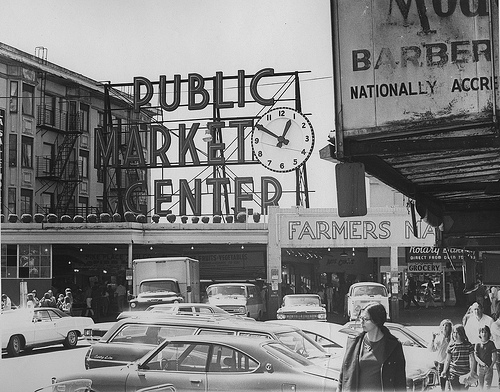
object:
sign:
[280, 213, 437, 243]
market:
[6, 184, 448, 316]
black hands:
[275, 119, 292, 148]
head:
[118, 279, 124, 285]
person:
[113, 281, 128, 307]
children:
[433, 301, 498, 383]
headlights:
[274, 311, 286, 318]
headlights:
[318, 311, 328, 320]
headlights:
[131, 302, 136, 308]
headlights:
[237, 305, 248, 314]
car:
[52, 333, 344, 390]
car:
[344, 279, 391, 304]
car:
[272, 292, 331, 322]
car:
[204, 281, 266, 319]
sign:
[88, 55, 321, 220]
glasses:
[356, 313, 371, 323]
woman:
[333, 300, 410, 390]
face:
[358, 306, 377, 334]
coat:
[339, 329, 409, 389]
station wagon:
[18, 267, 425, 389]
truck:
[130, 258, 198, 300]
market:
[4, 216, 285, 309]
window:
[208, 345, 259, 367]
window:
[142, 340, 211, 368]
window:
[111, 323, 191, 338]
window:
[32, 310, 45, 316]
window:
[48, 308, 60, 315]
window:
[198, 330, 233, 337]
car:
[87, 312, 315, 365]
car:
[1, 297, 96, 355]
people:
[3, 288, 75, 318]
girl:
[440, 317, 471, 390]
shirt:
[446, 340, 473, 371]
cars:
[50, 305, 340, 384]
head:
[63, 296, 71, 303]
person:
[61, 296, 71, 315]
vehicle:
[48, 332, 341, 389]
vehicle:
[342, 279, 394, 321]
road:
[0, 309, 497, 390]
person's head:
[440, 320, 450, 329]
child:
[432, 317, 452, 389]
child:
[474, 323, 495, 390]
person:
[331, 279, 346, 313]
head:
[325, 283, 337, 291]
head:
[359, 301, 386, 333]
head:
[439, 316, 453, 333]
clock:
[236, 86, 336, 178]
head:
[451, 323, 472, 340]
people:
[331, 292, 499, 389]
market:
[329, 2, 499, 226]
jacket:
[339, 328, 408, 388]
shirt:
[356, 329, 385, 389]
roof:
[20, 210, 275, 243]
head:
[470, 300, 483, 318]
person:
[332, 301, 406, 390]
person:
[433, 319, 448, 384]